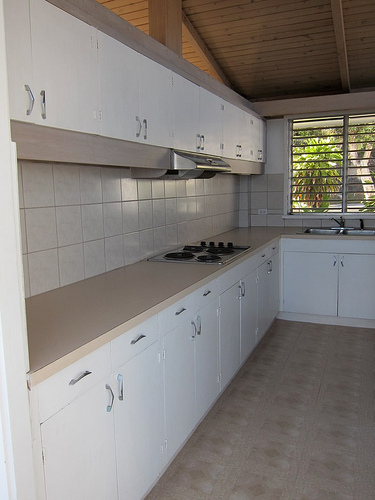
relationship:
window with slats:
[289, 116, 374, 216] [287, 110, 362, 212]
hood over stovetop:
[131, 152, 231, 181] [145, 237, 253, 266]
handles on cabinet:
[102, 370, 128, 409] [1, 223, 282, 498]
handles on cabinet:
[186, 315, 206, 341] [162, 304, 220, 469]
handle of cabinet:
[22, 82, 34, 118] [0, 0, 36, 126]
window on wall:
[289, 116, 375, 216] [253, 111, 339, 223]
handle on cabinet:
[24, 82, 34, 117] [281, 243, 373, 327]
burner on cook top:
[161, 250, 196, 261] [143, 238, 254, 266]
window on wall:
[289, 116, 375, 216] [241, 118, 373, 233]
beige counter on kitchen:
[24, 220, 284, 364] [2, 2, 373, 493]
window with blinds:
[289, 116, 375, 216] [294, 119, 373, 208]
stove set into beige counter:
[144, 241, 250, 265] [27, 227, 281, 390]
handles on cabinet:
[130, 110, 155, 142] [64, 6, 197, 151]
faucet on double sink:
[329, 214, 346, 227] [304, 225, 375, 237]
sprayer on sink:
[354, 215, 371, 230] [308, 223, 342, 235]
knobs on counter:
[207, 232, 231, 246] [103, 259, 152, 326]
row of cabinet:
[11, 4, 279, 175] [9, 0, 92, 139]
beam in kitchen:
[146, 0, 184, 57] [0, 0, 374, 500]